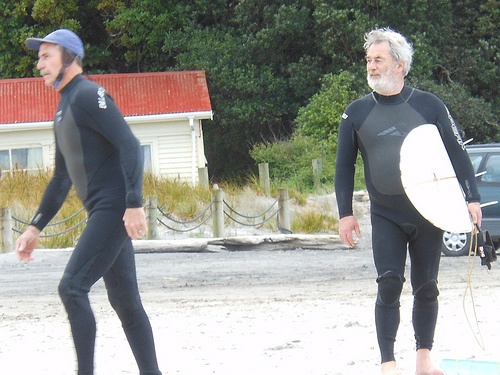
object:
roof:
[0, 62, 214, 125]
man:
[13, 31, 161, 373]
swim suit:
[29, 72, 165, 371]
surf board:
[398, 121, 488, 236]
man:
[335, 24, 486, 373]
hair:
[360, 25, 415, 58]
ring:
[137, 228, 144, 236]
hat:
[22, 27, 88, 88]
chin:
[46, 78, 65, 92]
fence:
[1, 184, 287, 252]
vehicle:
[438, 142, 500, 259]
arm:
[434, 90, 478, 208]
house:
[1, 65, 212, 228]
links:
[154, 220, 214, 237]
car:
[435, 139, 500, 257]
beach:
[2, 182, 500, 372]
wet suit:
[333, 84, 483, 362]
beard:
[364, 75, 397, 97]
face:
[363, 43, 405, 92]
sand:
[198, 282, 348, 369]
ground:
[210, 258, 327, 327]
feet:
[408, 348, 452, 373]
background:
[1, 3, 499, 266]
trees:
[289, 62, 341, 155]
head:
[35, 28, 89, 89]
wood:
[134, 223, 362, 254]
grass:
[163, 175, 204, 214]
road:
[3, 279, 59, 370]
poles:
[279, 185, 299, 253]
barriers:
[148, 183, 219, 239]